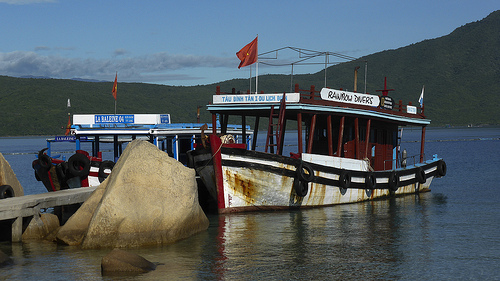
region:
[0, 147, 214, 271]
Four large rocks by dock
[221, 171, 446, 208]
Rust stains on side of boat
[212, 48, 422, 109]
Seating area on second deck of boat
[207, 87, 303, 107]
Writing in Vietnamese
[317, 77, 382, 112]
"Rainbow Divers"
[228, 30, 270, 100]
Red Vietnamese flag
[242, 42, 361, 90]
Frame for tarp that may be used on a rainy day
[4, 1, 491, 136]
Jungle terrain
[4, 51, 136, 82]
Cloud may rain just a little bit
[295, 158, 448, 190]
Rubber tires tied to side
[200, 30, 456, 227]
boat docked by a pier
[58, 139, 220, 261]
large rock in the water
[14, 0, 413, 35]
dark blue sky in the background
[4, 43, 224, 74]
clouds in the sky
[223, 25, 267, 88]
red flag on top of boat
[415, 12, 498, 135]
green mountains in the distance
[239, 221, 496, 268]
water where the boats are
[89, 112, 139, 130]
blue sign on a boat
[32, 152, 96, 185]
black life preservers on boat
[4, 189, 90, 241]
pier leading to the boats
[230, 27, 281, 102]
a small red flag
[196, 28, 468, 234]
a small tour boat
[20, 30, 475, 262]
tour boats at a dock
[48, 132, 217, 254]
a large boulder in water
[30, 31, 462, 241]
red, white, and blue tour boats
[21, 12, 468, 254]
tour boats on water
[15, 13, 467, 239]
boats at a dock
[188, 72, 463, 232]
a boat with a gazebo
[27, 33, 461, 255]
two small tour boats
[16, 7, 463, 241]
tour boats surrounded by mountains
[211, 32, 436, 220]
small Vietnamese ferry boat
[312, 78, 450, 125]
sign for Rainbow Divers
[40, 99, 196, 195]
two Vietnamese ferry boats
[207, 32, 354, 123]
Vietnamese flag on boat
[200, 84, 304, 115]
sign written in Vietnamese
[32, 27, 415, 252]
three boats docked near rock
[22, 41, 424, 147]
hills in the distance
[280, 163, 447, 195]
tires tied to boat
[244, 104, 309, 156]
ladder to top of boat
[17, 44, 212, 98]
clouds in blue sky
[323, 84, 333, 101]
the black letter R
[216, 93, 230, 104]
the blue letter T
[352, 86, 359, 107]
the black letter D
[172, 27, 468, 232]
this is a boat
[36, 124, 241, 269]
this is a large rock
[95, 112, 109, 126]
the white letter B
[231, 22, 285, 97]
a high red flag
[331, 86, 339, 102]
a black letter A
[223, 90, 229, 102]
a blue letter A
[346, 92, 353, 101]
the black letter W